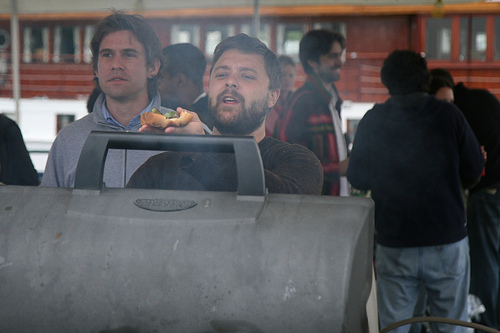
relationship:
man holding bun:
[123, 31, 328, 195] [138, 108, 191, 129]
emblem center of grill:
[116, 185, 215, 220] [1, 124, 390, 331]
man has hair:
[123, 31, 328, 195] [215, 33, 274, 54]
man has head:
[123, 31, 328, 195] [199, 35, 294, 134]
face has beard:
[199, 29, 280, 129] [202, 82, 271, 136]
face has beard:
[205, 49, 270, 125] [309, 55, 344, 82]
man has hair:
[123, 31, 328, 195] [219, 26, 283, 62]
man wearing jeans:
[349, 47, 486, 331] [374, 239, 475, 331]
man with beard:
[123, 31, 328, 195] [201, 87, 280, 139]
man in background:
[343, 47, 488, 332] [152, 7, 484, 97]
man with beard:
[123, 31, 328, 195] [293, 25, 346, 95]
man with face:
[123, 31, 328, 195] [204, 40, 275, 131]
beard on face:
[293, 25, 346, 95] [204, 40, 275, 131]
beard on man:
[293, 25, 346, 95] [123, 31, 328, 195]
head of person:
[85, 15, 163, 103] [45, 5, 183, 204]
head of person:
[89, 12, 163, 100] [338, 32, 486, 325]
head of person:
[89, 12, 163, 100] [343, 47, 490, 332]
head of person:
[89, 12, 163, 100] [437, 68, 487, 185]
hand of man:
[163, 105, 201, 136] [172, 32, 318, 192]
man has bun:
[162, 34, 309, 205] [139, 105, 184, 143]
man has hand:
[162, 34, 309, 205] [144, 95, 212, 134]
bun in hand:
[139, 105, 184, 143] [144, 95, 212, 134]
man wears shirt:
[343, 47, 488, 332] [449, 77, 497, 179]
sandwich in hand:
[137, 95, 219, 134] [140, 99, 227, 151]